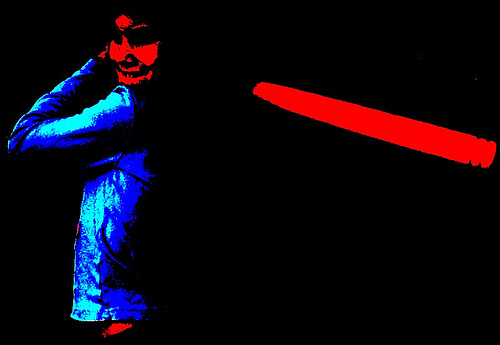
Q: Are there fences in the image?
A: No, there are no fences.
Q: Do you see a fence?
A: No, there are no fences.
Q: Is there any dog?
A: No, there are no dogs.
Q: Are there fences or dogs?
A: No, there are no dogs or fences.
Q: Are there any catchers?
A: No, there are no catchers.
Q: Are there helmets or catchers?
A: No, there are no catchers or helmets.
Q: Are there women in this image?
A: Yes, there is a woman.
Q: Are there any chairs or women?
A: Yes, there is a woman.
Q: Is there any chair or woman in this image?
A: Yes, there is a woman.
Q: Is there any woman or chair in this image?
A: Yes, there is a woman.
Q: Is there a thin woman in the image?
A: Yes, there is a thin woman.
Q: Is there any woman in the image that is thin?
A: Yes, there is a woman that is thin.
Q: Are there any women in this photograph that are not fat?
A: Yes, there is a thin woman.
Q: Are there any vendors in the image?
A: No, there are no vendors.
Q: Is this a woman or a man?
A: This is a woman.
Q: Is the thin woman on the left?
A: Yes, the woman is on the left of the image.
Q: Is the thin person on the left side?
A: Yes, the woman is on the left of the image.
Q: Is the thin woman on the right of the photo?
A: No, the woman is on the left of the image.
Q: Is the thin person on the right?
A: No, the woman is on the left of the image.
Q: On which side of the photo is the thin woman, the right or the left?
A: The woman is on the left of the image.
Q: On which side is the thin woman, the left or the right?
A: The woman is on the left of the image.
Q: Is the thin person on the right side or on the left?
A: The woman is on the left of the image.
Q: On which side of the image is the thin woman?
A: The woman is on the left of the image.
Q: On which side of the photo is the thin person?
A: The woman is on the left of the image.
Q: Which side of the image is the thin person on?
A: The woman is on the left of the image.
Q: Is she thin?
A: Yes, the woman is thin.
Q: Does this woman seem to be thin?
A: Yes, the woman is thin.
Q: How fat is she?
A: The woman is thin.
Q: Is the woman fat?
A: No, the woman is thin.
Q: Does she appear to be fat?
A: No, the woman is thin.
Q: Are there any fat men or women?
A: No, there is a woman but she is thin.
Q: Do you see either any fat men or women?
A: No, there is a woman but she is thin.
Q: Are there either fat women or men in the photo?
A: No, there is a woman but she is thin.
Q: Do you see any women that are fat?
A: No, there is a woman but she is thin.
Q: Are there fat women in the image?
A: No, there is a woman but she is thin.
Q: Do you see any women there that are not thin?
A: No, there is a woman but she is thin.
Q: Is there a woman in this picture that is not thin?
A: No, there is a woman but she is thin.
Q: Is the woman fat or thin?
A: The woman is thin.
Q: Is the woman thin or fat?
A: The woman is thin.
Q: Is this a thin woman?
A: Yes, this is a thin woman.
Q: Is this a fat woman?
A: No, this is a thin woman.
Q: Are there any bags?
A: No, there are no bags.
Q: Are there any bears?
A: No, there are no bears.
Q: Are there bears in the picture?
A: No, there are no bears.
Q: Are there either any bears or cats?
A: No, there are no bears or cats.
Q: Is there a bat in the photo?
A: Yes, there is a bat.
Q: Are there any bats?
A: Yes, there is a bat.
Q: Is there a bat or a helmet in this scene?
A: Yes, there is a bat.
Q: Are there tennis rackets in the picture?
A: No, there are no tennis rackets.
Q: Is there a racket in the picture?
A: No, there are no rackets.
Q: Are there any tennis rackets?
A: No, there are no tennis rackets.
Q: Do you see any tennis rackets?
A: No, there are no tennis rackets.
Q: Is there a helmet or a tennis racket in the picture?
A: No, there are no rackets or helmets.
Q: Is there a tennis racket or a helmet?
A: No, there are no rackets or helmets.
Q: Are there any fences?
A: No, there are no fences.